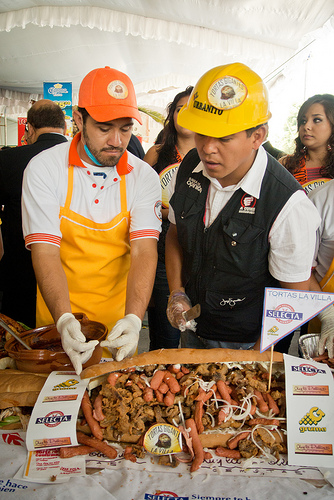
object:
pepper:
[174, 426, 195, 464]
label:
[34, 410, 72, 448]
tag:
[295, 443, 333, 454]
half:
[79, 348, 283, 382]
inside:
[86, 361, 285, 432]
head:
[73, 67, 134, 166]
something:
[284, 103, 302, 154]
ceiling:
[0, 0, 334, 89]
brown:
[79, 348, 282, 380]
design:
[292, 364, 327, 377]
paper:
[283, 355, 334, 468]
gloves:
[100, 313, 141, 361]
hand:
[61, 315, 99, 376]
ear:
[253, 124, 268, 150]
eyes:
[314, 118, 322, 123]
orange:
[77, 65, 141, 124]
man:
[21, 66, 163, 376]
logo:
[102, 82, 132, 91]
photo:
[0, 0, 333, 499]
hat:
[177, 62, 273, 139]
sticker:
[207, 76, 248, 111]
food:
[0, 354, 333, 473]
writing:
[291, 364, 326, 376]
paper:
[292, 364, 330, 395]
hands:
[100, 317, 139, 362]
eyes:
[301, 120, 306, 124]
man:
[0, 99, 69, 329]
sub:
[60, 362, 285, 475]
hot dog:
[185, 418, 204, 473]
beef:
[91, 363, 286, 458]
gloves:
[56, 313, 100, 375]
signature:
[220, 297, 246, 306]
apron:
[35, 164, 137, 363]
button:
[87, 170, 118, 203]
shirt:
[21, 130, 163, 250]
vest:
[169, 146, 308, 344]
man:
[164, 62, 320, 351]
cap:
[78, 66, 144, 125]